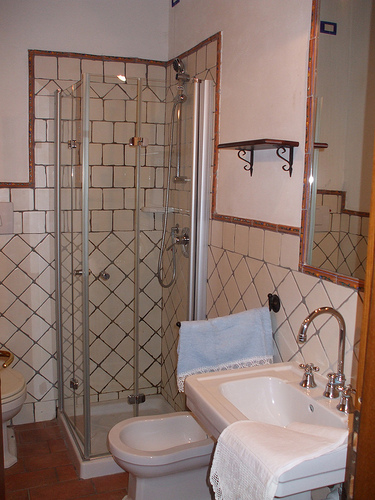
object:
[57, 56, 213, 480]
shower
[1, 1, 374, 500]
bathroom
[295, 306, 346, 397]
faucet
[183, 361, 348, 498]
sink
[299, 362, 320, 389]
handle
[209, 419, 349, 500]
towel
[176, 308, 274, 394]
towel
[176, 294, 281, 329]
rack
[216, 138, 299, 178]
shelf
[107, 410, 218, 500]
bidet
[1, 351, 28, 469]
toilet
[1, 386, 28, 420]
bowl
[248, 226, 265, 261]
tile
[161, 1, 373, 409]
wall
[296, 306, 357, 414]
fixtures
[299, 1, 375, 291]
mirror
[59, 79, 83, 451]
doors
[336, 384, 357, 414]
handle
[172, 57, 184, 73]
showerhead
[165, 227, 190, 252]
water control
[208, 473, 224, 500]
trim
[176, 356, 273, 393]
trim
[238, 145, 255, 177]
supports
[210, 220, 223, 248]
tile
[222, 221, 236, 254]
tile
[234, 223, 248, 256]
tile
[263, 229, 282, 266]
tile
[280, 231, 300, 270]
tile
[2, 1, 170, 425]
wall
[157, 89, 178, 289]
shower hose